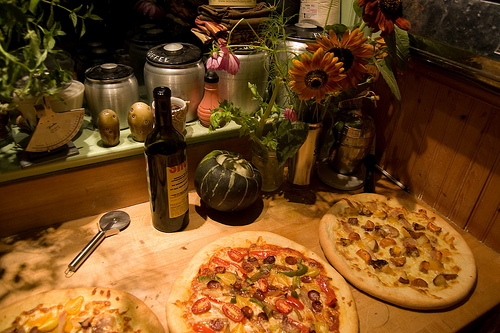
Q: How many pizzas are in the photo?
A: 3.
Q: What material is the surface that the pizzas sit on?
A: Wood.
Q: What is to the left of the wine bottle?
A: A pizza cutter.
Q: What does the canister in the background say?
A: COFFEE.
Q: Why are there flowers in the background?
A: Decoration.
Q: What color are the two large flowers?
A: Orange.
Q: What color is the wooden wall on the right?
A: Brown.